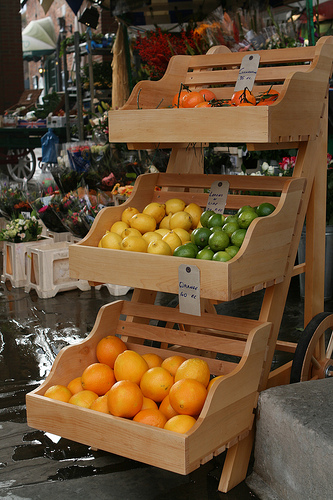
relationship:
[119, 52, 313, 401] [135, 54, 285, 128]
cart with shelf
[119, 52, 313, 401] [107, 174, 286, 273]
cart with shelf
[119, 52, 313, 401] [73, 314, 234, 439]
cart with shelf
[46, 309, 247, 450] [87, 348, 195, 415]
shelf with oranges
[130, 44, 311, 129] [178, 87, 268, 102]
shelf with tangerines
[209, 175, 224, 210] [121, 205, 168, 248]
tag for lemons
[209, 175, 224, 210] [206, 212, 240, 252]
tag for limes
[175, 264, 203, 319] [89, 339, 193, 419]
tag for oranges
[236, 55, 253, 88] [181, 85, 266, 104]
tag for clementines